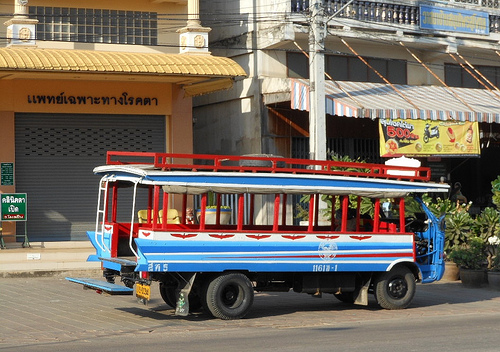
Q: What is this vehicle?
A: A trolley.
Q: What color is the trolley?
A: Blue, Red, and White.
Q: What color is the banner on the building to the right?
A: Yellow.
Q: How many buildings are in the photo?
A: 2.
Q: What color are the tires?
A: Black.